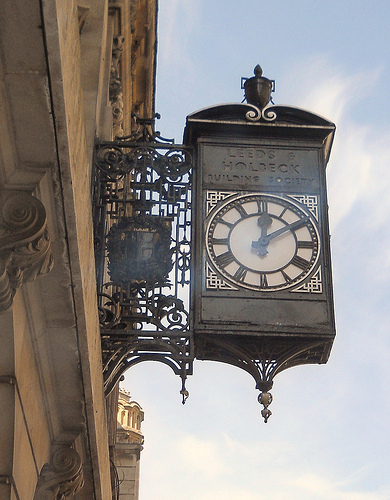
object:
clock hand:
[258, 214, 311, 245]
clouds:
[119, 12, 390, 431]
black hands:
[252, 211, 274, 256]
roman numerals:
[234, 266, 247, 283]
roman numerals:
[217, 250, 235, 268]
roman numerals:
[218, 217, 233, 228]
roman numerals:
[234, 203, 248, 218]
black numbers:
[257, 199, 268, 212]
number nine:
[213, 238, 229, 245]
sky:
[121, 0, 388, 499]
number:
[279, 206, 289, 217]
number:
[290, 219, 307, 230]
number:
[298, 240, 314, 248]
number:
[291, 255, 309, 269]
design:
[32, 430, 86, 498]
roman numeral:
[217, 251, 234, 269]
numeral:
[281, 270, 292, 282]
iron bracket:
[93, 111, 195, 398]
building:
[3, 0, 336, 500]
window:
[110, 40, 154, 109]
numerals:
[260, 273, 268, 287]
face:
[205, 190, 322, 294]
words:
[208, 149, 311, 185]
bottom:
[192, 329, 336, 423]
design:
[201, 188, 327, 301]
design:
[245, 103, 277, 122]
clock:
[202, 189, 326, 301]